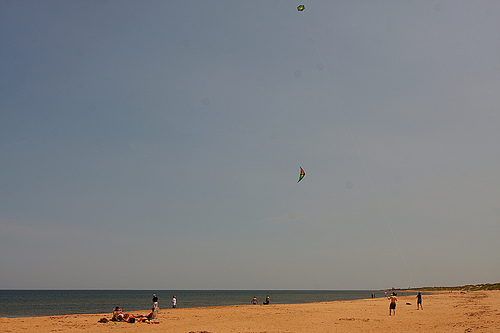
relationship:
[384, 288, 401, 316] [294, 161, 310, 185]
man flying a kite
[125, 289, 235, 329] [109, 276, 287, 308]
people walking near water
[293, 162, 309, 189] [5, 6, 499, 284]
kite in sky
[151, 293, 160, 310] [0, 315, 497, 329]
people sitting on sand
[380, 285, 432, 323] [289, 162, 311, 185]
people flying kite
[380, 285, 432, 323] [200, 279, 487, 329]
people on beach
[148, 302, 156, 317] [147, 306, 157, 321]
person sitting in a chair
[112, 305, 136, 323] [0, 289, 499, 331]
person sitting in sand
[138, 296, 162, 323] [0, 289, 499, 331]
person sitting in sand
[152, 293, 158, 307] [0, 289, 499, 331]
person sitting in sand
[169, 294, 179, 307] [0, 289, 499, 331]
person sitting in sand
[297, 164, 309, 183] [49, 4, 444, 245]
kite in air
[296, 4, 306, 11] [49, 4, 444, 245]
kite in air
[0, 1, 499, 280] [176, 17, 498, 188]
clouds in sky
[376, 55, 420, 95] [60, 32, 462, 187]
clouds in sky